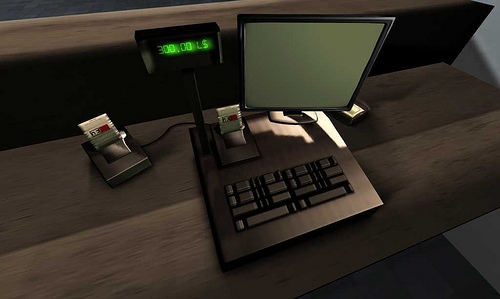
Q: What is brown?
A: The counter.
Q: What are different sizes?
A: The buttons.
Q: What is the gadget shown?
A: Money register.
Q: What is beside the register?
A: Electronic box.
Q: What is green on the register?
A: The writing.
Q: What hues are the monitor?
A: Black and gray.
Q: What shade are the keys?
A: Black.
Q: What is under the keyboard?
A: Dark table.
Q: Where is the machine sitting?
A: Dark countertop.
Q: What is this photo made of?
A: Computerized.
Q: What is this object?
A: A computer.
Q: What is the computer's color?
A: Black.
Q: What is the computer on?
A: Table.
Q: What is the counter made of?
A: Wood.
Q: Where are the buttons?
A: On the keyboard.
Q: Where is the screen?
A: On the monitor.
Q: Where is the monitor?
A: On the desk.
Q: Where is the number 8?
A: On the screen.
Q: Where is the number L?
A: On the screen.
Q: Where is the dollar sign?
A: On the sign.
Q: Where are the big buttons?
A: On the screen.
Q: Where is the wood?
A: On the desk.